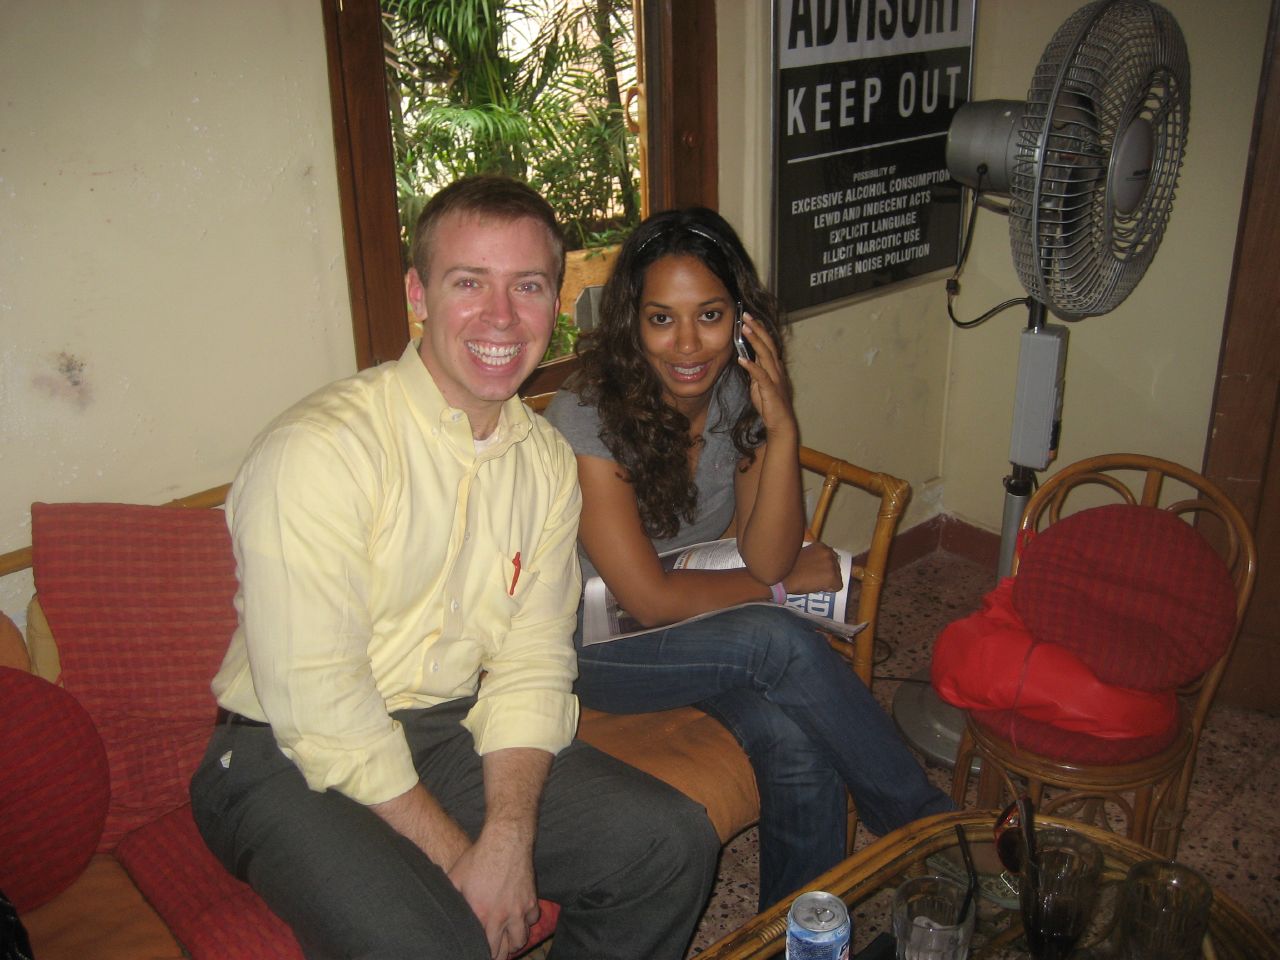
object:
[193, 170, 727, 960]
male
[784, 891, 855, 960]
drink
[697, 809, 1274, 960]
table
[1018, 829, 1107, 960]
tumblers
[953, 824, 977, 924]
straws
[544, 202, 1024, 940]
female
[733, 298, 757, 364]
phone